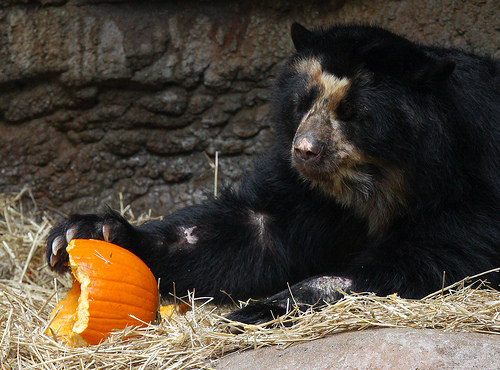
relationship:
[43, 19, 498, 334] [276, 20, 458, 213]
animal has head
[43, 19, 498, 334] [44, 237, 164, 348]
animal holding on a fruit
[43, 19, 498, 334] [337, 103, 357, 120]
animal has eye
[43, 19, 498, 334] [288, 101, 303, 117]
animal has eye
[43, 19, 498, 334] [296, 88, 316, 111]
animal has eye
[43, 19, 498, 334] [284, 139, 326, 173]
animal has nose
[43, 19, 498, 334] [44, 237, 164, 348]
animal holding onto fruit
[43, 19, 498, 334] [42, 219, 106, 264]
animal has claws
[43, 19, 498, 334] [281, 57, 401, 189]
animal has face